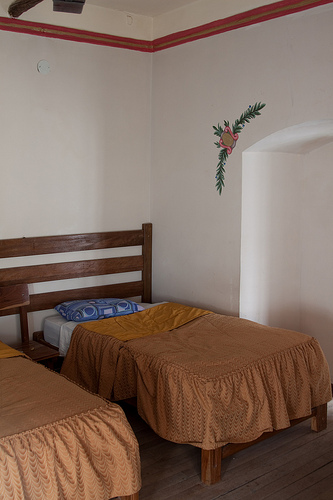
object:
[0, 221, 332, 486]
beds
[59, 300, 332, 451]
sheets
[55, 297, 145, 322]
pillow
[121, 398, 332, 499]
floor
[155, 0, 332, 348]
walls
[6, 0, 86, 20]
wood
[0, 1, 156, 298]
wall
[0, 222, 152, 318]
headboard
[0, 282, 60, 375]
chair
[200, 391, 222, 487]
legs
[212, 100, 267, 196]
decoration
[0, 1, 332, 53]
boarder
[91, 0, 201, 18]
ceiling